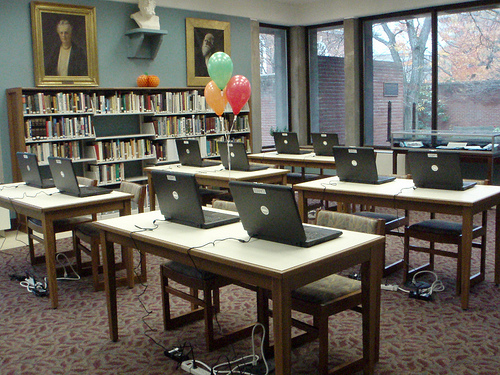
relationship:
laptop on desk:
[148, 171, 234, 228] [94, 203, 242, 360]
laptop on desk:
[229, 180, 339, 248] [193, 217, 384, 374]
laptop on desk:
[49, 157, 117, 197] [19, 191, 130, 307]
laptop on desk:
[18, 153, 50, 188] [0, 176, 135, 301]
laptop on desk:
[335, 147, 399, 185] [300, 171, 405, 224]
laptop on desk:
[407, 147, 485, 190] [397, 178, 499, 311]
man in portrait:
[53, 19, 84, 76] [29, 1, 99, 90]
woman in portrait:
[199, 33, 215, 56] [184, 16, 231, 88]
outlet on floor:
[165, 345, 273, 374] [2, 179, 497, 372]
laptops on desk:
[275, 131, 347, 156] [251, 151, 335, 177]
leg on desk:
[41, 217, 58, 309] [19, 191, 130, 307]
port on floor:
[166, 346, 187, 360] [2, 179, 497, 372]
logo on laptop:
[257, 204, 271, 217] [229, 180, 339, 248]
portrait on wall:
[29, 1, 99, 90] [1, 1, 257, 236]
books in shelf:
[23, 93, 143, 116] [6, 84, 158, 230]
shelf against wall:
[6, 84, 158, 230] [1, 1, 257, 236]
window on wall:
[259, 25, 290, 149] [1, 1, 257, 236]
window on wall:
[437, 10, 499, 144] [294, 1, 499, 151]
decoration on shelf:
[135, 73, 159, 88] [6, 84, 158, 230]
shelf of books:
[6, 84, 158, 230] [23, 93, 143, 116]